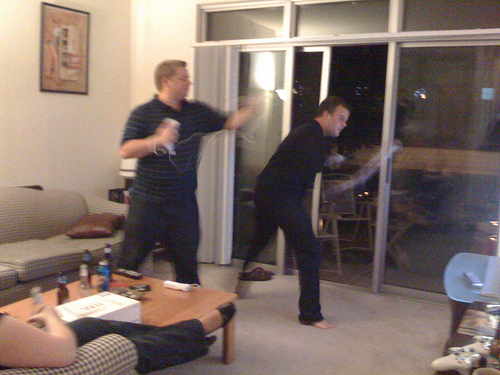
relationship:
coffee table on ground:
[0, 272, 239, 364] [153, 259, 493, 372]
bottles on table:
[54, 270, 159, 310] [92, 274, 342, 356]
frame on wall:
[35, 2, 92, 97] [4, 3, 131, 185]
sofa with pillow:
[0, 179, 141, 299] [65, 212, 124, 238]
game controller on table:
[158, 278, 194, 292] [24, 237, 263, 373]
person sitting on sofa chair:
[0, 301, 237, 375] [0, 324, 144, 374]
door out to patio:
[239, 42, 391, 295] [241, 40, 498, 301]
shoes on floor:
[232, 265, 275, 279] [149, 262, 452, 373]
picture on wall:
[42, 4, 88, 93] [19, 113, 104, 175]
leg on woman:
[60, 315, 220, 354] [2, 297, 236, 373]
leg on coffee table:
[107, 300, 241, 372] [0, 262, 241, 373]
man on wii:
[95, 33, 273, 291] [145, 102, 203, 176]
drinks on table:
[72, 240, 118, 302] [0, 251, 245, 371]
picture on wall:
[37, 0, 94, 97] [1, 0, 131, 206]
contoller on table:
[430, 342, 491, 374] [179, 274, 239, 324]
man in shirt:
[118, 61, 273, 278] [116, 90, 226, 191]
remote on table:
[113, 262, 141, 281] [65, 253, 233, 347]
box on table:
[45, 289, 144, 325] [1, 265, 237, 365]